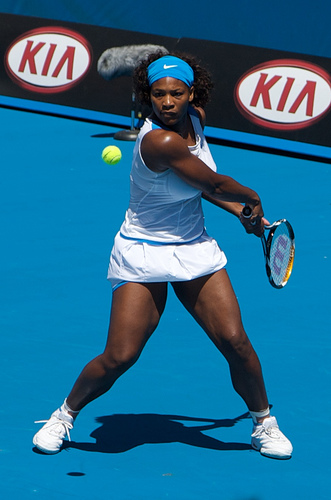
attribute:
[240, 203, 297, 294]
tennisracket — wilson 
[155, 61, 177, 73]
logo — white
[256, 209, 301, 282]
racket — black, yellow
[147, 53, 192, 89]
headband — Blue, nike sports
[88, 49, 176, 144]
stand — black 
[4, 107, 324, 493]
floor — Blue 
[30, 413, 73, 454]
shoe — White 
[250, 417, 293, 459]
shoe — White 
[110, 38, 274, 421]
player — african american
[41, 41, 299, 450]
women — playing tennis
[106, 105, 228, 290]
dress — White 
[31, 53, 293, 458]
player — tennis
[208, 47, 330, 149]
advertisement — kia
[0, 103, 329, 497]
court — blue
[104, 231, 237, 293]
skirt — white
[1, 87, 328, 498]
ground — dark blue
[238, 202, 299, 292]
tennis racket — black and orange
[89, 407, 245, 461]
shadow — tennis player, tennis ball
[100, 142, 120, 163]
ball — YELLOW, TENNIS, WHITE STRIPED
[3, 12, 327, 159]
sign — red, black , white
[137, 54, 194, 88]
head band — blue